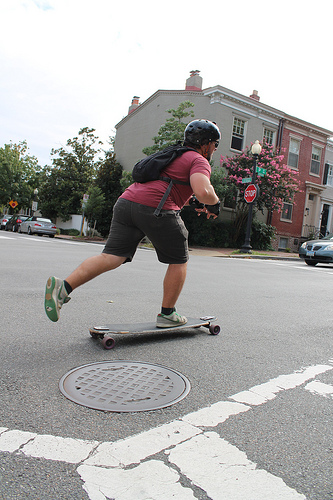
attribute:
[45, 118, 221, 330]
skateboarder — male, skateboarding, man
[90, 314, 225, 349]
skateboard — wooden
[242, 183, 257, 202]
stop sign — red, white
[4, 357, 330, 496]
lines — white, cracked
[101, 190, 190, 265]
shorts — dark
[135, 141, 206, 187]
backpack — black, small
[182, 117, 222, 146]
helmet — black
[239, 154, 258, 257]
light pole — metal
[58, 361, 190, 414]
manhole — metal, pictured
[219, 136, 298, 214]
flowers — pink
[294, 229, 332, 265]
car — driving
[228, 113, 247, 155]
window — open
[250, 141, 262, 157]
streetlight — white, tall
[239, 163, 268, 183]
street signs — green